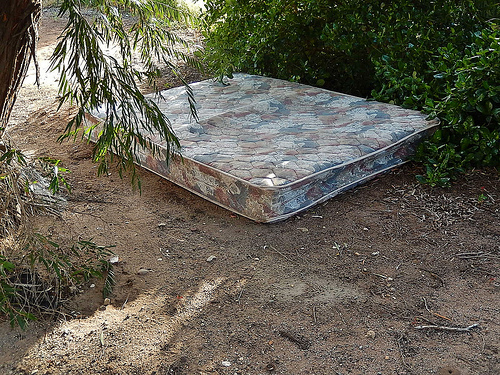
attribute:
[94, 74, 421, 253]
mattress — big size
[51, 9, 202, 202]
branches — leaf covered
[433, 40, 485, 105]
leaves — green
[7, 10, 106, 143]
trunk — gnarled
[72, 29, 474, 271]
matress — abandoned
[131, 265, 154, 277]
rock — small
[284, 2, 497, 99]
tree — green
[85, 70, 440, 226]
mattress — dirty, multi color, queen size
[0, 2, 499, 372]
pathway — dirt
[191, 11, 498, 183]
bush — green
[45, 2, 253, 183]
leafy/tree branch — hanging down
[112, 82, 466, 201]
print — colorful, floral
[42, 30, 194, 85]
sunlight — area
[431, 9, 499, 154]
leaves — dark green